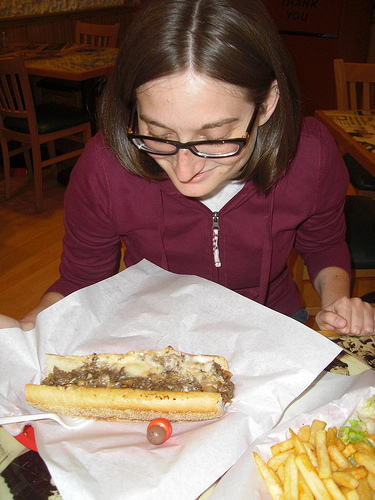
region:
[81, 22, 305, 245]
woman in glasses in photo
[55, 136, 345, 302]
woman wearing maroon sweater with zipper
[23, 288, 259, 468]
cheesesteak on white paper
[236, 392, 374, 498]
side of fries with lettuce on plate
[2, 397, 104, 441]
white plastic fork under cheesesteak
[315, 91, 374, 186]
square brown table in background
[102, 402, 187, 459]
something red and brown next to cheesesteak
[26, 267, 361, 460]
food on white paper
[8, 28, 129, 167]
square table with two brown chairs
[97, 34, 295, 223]
woman with brown hair and black eyeglasses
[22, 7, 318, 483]
woman looking down at sandwich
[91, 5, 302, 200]
brown hair curled around face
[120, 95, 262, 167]
dark eyeglass frames below eyebrows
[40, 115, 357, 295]
plum-colored top with zipper in front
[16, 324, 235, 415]
beef and melted cheese on long bread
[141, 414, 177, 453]
small orange and brown object next to sandwich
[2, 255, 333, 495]
crinkled white paper under sandwich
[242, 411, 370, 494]
pile of golden french fries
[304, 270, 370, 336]
curled hand leaning on table edge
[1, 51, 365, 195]
table and chairs behind woman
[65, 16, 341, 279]
women wearing a maroon jacket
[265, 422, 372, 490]
french fries in a tray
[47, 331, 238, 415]
cheese steak on a piece of white paper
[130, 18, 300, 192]
woman wearing eye glasses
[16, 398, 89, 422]
white fork on a plate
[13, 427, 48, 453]
red plate with a cheese steak on it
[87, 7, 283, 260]
woman wearing a white t shirt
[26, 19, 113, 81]
wood table in a restaurant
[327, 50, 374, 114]
wood chair in a restaruant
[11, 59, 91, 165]
wood chair in a restaruant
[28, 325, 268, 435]
A sandwich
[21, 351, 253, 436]
A sandwich on white paper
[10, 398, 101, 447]
A white plastic fork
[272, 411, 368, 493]
French fries on white paper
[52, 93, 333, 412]
A woman looking at a sandwich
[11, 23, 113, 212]
A table and two chairs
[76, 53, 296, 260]
The head of a woman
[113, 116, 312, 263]
A woman wearing glasses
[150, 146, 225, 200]
the nose of a woman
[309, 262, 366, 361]
the hand of a woman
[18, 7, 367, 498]
woman getting ready to eat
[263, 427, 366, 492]
pile of golden yellow french fries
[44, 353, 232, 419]
philly sandwich on sub bun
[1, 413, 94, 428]
white plastic fork under sandwich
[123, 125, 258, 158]
brown eyeglasses on woman's face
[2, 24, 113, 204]
empty decorative dining table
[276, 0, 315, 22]
thank you sign on door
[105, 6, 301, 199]
woman with brown hair is smiling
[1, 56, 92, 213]
empty wooden chair with black seat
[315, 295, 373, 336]
hand in a fist is sitting on table